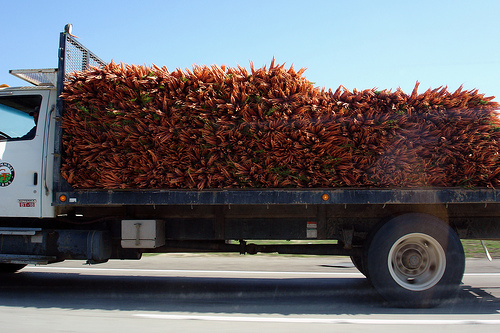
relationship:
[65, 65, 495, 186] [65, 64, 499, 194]
plants are pile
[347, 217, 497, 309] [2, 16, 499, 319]
tire on truck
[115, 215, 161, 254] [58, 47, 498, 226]
white box under truck trailer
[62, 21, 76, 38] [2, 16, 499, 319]
bird perched on truck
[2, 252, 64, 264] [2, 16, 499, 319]
step on truck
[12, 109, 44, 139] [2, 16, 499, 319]
driver has truck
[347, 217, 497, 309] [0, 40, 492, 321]
tire on truck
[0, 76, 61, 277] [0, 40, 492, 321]
front of truck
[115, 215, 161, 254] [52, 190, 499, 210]
white box are on flatbed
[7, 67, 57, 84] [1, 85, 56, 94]
wire ledge over truck roof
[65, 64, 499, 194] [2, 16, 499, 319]
pile on truck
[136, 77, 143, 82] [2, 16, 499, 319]
plant on truck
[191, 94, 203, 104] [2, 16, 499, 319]
plant on truck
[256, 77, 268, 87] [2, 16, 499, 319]
plant on truck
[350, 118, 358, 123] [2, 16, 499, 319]
plant on truck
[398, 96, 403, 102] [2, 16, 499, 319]
plant on truck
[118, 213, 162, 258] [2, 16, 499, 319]
box on truck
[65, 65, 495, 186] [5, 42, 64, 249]
plants on back truck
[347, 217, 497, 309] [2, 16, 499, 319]
tire on back truck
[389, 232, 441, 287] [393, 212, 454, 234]
rim on truck tire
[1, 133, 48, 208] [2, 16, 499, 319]
cab on truck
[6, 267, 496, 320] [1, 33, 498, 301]
shadow on truck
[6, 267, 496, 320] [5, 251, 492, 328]
shadow on ground